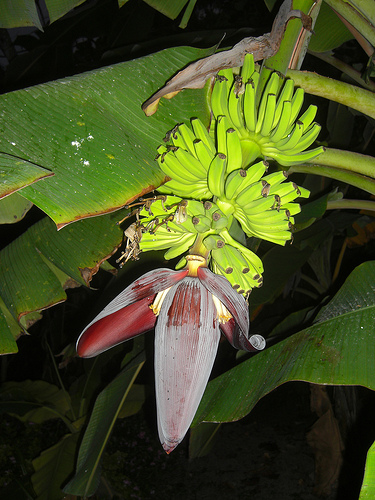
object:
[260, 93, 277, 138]
banana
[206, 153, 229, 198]
banana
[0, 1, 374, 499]
tree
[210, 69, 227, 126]
banana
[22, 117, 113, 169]
spots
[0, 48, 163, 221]
leaf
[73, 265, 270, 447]
flower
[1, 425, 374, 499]
ground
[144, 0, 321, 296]
stem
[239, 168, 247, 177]
end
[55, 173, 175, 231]
edge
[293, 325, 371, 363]
vein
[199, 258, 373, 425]
leaf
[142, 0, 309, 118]
leaf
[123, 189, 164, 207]
twig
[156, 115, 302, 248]
bushel